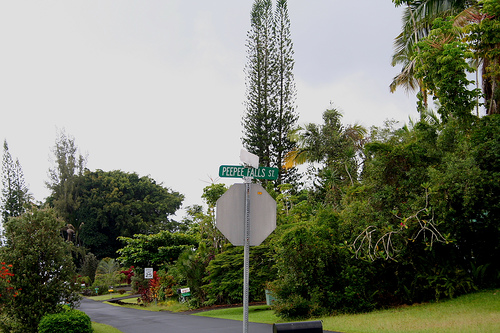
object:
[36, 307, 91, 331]
bush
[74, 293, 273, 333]
road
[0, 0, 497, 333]
residential area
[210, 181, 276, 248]
sign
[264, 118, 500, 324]
bushes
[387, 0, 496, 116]
palm tree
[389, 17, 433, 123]
palm tree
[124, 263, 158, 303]
plant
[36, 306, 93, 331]
green bush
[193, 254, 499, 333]
grass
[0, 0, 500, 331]
photo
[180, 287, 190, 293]
mailbox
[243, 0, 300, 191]
tree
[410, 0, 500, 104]
leaves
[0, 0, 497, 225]
daytime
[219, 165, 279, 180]
green sign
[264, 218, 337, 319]
tree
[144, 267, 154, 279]
sign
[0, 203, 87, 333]
trees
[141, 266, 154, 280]
speedlimit sign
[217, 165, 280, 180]
sign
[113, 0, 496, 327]
forest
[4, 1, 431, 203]
sky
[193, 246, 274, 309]
tree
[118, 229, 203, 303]
tree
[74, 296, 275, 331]
roadside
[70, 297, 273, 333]
street